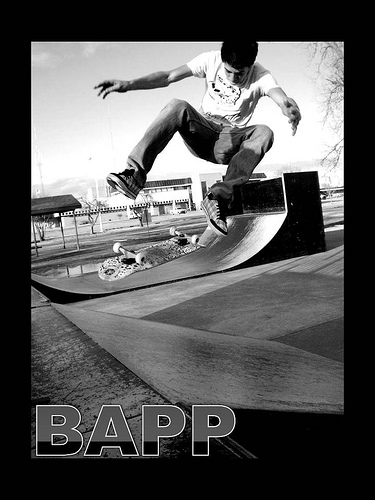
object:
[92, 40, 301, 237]
guy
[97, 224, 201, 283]
skateboard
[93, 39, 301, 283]
kick flip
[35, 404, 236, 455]
decoration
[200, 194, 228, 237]
shoe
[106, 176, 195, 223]
building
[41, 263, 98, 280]
water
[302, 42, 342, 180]
tree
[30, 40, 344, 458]
picture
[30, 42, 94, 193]
air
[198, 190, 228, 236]
sneakers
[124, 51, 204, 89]
arms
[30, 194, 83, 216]
canopy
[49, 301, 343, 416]
ramp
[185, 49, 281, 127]
t-shirt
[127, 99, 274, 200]
jeans